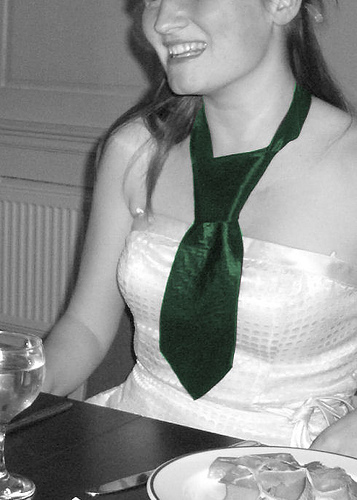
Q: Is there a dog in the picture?
A: No, there are no dogs.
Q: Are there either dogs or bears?
A: No, there are no dogs or bears.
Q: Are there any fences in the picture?
A: No, there are no fences.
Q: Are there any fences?
A: No, there are no fences.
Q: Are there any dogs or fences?
A: No, there are no fences or dogs.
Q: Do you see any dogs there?
A: No, there are no dogs.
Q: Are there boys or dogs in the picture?
A: No, there are no dogs or boys.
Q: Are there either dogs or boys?
A: No, there are no dogs or boys.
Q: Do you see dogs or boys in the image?
A: No, there are no dogs or boys.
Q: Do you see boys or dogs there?
A: No, there are no dogs or boys.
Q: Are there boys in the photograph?
A: No, there are no boys.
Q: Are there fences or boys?
A: No, there are no boys or fences.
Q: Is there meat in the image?
A: Yes, there is meat.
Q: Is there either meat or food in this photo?
A: Yes, there is meat.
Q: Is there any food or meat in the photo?
A: Yes, there is meat.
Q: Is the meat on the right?
A: Yes, the meat is on the right of the image.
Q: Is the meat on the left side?
A: No, the meat is on the right of the image.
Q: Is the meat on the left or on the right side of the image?
A: The meat is on the right of the image.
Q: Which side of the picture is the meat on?
A: The meat is on the right of the image.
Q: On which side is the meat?
A: The meat is on the right of the image.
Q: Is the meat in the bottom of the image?
A: Yes, the meat is in the bottom of the image.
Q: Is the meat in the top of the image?
A: No, the meat is in the bottom of the image.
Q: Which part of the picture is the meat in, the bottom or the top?
A: The meat is in the bottom of the image.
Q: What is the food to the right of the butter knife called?
A: The food is meat.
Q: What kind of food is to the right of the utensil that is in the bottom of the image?
A: The food is meat.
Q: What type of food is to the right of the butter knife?
A: The food is meat.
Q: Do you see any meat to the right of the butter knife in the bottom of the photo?
A: Yes, there is meat to the right of the butter knife.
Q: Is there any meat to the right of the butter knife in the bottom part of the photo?
A: Yes, there is meat to the right of the butter knife.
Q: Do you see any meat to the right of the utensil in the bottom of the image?
A: Yes, there is meat to the right of the butter knife.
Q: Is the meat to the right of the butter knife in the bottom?
A: Yes, the meat is to the right of the butter knife.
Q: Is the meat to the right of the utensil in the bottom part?
A: Yes, the meat is to the right of the butter knife.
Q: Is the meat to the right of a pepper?
A: No, the meat is to the right of the butter knife.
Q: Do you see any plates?
A: Yes, there is a plate.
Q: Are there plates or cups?
A: Yes, there is a plate.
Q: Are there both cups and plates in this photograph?
A: No, there is a plate but no cups.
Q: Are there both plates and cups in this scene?
A: No, there is a plate but no cups.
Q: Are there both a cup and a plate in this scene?
A: No, there is a plate but no cups.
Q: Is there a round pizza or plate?
A: Yes, there is a round plate.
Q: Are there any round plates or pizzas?
A: Yes, there is a round plate.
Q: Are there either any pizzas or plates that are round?
A: Yes, the plate is round.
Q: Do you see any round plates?
A: Yes, there is a round plate.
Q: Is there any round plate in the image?
A: Yes, there is a round plate.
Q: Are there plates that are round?
A: Yes, there is a plate that is round.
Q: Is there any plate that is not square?
A: Yes, there is a round plate.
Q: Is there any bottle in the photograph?
A: No, there are no bottles.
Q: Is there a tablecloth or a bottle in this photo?
A: No, there are no bottles or tablecloths.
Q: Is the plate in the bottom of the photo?
A: Yes, the plate is in the bottom of the image.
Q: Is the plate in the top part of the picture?
A: No, the plate is in the bottom of the image.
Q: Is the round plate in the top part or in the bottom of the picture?
A: The plate is in the bottom of the image.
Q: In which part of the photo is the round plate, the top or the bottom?
A: The plate is in the bottom of the image.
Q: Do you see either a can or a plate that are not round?
A: No, there is a plate but it is round.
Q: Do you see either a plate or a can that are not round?
A: No, there is a plate but it is round.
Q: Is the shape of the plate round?
A: Yes, the plate is round.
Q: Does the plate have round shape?
A: Yes, the plate is round.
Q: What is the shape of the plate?
A: The plate is round.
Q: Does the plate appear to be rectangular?
A: No, the plate is round.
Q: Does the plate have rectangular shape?
A: No, the plate is round.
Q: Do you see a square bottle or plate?
A: No, there is a plate but it is round.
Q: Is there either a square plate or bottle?
A: No, there is a plate but it is round.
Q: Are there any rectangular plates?
A: No, there is a plate but it is round.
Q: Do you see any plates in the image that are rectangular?
A: No, there is a plate but it is round.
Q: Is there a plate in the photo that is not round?
A: No, there is a plate but it is round.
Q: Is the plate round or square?
A: The plate is round.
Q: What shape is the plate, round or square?
A: The plate is round.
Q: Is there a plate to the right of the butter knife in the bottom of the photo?
A: Yes, there is a plate to the right of the butter knife.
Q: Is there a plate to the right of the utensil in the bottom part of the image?
A: Yes, there is a plate to the right of the butter knife.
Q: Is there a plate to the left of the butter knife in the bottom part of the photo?
A: No, the plate is to the right of the butter knife.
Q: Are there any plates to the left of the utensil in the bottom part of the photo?
A: No, the plate is to the right of the butter knife.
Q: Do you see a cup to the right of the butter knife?
A: No, there is a plate to the right of the butter knife.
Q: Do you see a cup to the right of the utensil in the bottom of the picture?
A: No, there is a plate to the right of the butter knife.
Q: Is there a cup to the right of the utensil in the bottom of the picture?
A: No, there is a plate to the right of the butter knife.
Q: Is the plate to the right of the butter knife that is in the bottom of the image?
A: Yes, the plate is to the right of the butter knife.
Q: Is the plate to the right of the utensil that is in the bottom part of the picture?
A: Yes, the plate is to the right of the butter knife.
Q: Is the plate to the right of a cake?
A: No, the plate is to the right of the butter knife.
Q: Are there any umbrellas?
A: No, there are no umbrellas.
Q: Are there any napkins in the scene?
A: No, there are no napkins.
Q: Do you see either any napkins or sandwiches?
A: No, there are no napkins or sandwiches.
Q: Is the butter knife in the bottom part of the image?
A: Yes, the butter knife is in the bottom of the image.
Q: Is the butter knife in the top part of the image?
A: No, the butter knife is in the bottom of the image.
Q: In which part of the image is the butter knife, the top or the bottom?
A: The butter knife is in the bottom of the image.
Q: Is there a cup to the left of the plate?
A: No, there is a butter knife to the left of the plate.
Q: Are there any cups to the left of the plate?
A: No, there is a butter knife to the left of the plate.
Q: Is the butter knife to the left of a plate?
A: Yes, the butter knife is to the left of a plate.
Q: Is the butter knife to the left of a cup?
A: No, the butter knife is to the left of a plate.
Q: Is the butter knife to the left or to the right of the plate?
A: The butter knife is to the left of the plate.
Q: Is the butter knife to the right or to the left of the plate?
A: The butter knife is to the left of the plate.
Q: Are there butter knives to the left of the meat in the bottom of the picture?
A: Yes, there is a butter knife to the left of the meat.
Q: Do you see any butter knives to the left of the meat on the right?
A: Yes, there is a butter knife to the left of the meat.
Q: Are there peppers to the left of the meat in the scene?
A: No, there is a butter knife to the left of the meat.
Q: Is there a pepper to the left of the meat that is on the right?
A: No, there is a butter knife to the left of the meat.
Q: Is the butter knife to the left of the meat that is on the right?
A: Yes, the butter knife is to the left of the meat.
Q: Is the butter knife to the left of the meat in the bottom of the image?
A: Yes, the butter knife is to the left of the meat.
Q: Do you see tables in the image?
A: Yes, there is a table.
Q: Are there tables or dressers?
A: Yes, there is a table.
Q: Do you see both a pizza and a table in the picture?
A: No, there is a table but no pizzas.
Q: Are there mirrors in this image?
A: No, there are no mirrors.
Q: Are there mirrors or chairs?
A: No, there are no mirrors or chairs.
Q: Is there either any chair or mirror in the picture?
A: No, there are no mirrors or chairs.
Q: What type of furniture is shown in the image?
A: The furniture is a table.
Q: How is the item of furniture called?
A: The piece of furniture is a table.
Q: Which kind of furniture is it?
A: The piece of furniture is a table.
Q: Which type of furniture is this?
A: That is a table.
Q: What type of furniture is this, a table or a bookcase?
A: That is a table.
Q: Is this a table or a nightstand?
A: This is a table.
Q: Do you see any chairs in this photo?
A: No, there are no chairs.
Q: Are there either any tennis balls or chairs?
A: No, there are no chairs or tennis balls.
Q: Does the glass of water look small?
A: Yes, the glass is small.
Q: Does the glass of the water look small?
A: Yes, the glass is small.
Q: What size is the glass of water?
A: The glass is small.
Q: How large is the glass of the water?
A: The glass is small.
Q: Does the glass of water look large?
A: No, the glass is small.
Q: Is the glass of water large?
A: No, the glass is small.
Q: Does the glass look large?
A: No, the glass is small.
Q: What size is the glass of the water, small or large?
A: The glass is small.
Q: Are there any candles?
A: No, there are no candles.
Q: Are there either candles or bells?
A: No, there are no candles or bells.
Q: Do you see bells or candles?
A: No, there are no candles or bells.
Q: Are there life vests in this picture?
A: No, there are no life vests.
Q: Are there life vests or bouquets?
A: No, there are no life vests or bouquets.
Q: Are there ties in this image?
A: Yes, there is a tie.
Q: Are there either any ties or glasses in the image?
A: Yes, there is a tie.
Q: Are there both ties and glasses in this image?
A: Yes, there are both a tie and glasses.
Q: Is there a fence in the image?
A: No, there are no fences.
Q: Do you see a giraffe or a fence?
A: No, there are no fences or giraffes.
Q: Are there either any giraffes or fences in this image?
A: No, there are no fences or giraffes.